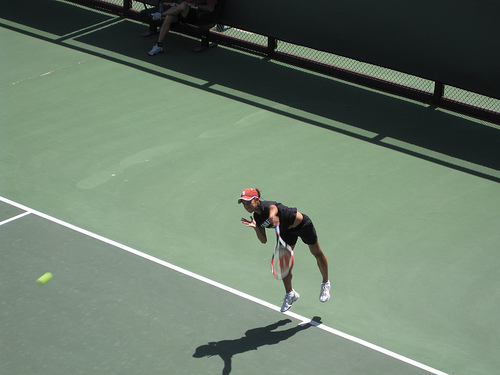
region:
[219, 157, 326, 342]
A woman holding a tennis racket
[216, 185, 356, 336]
a woman jumping up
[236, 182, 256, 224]
a woman wearing a red hat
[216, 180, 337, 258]
a woman wearing a black shirt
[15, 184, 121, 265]
white lines on the tennis court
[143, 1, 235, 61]
a person sitting on a bench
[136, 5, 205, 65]
a person with their legs crossed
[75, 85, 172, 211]
a green tennis court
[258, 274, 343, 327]
two feet off the ground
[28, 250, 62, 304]
a tennis ball in motion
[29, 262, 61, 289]
The ball flying through the air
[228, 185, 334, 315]
The player who just hit the ball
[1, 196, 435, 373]
The white lines on the court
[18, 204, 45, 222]
Where the white lines meet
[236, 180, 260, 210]
The red hat worn by the tennis player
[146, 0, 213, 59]
The person sitting on the bench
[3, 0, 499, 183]
The shadow on the ground behind the court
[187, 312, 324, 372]
The player's shadow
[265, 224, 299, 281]
The racket held by the player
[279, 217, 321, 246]
The player's black shorts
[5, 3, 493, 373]
tennis court on which woman is playing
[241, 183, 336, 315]
woman playing tennis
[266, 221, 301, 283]
woman's tennis racket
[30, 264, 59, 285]
ball in air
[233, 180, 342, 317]
tennis player in black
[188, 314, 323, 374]
shadow of woman tennis player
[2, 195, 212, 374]
baseline of tennis court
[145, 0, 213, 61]
person sitting on bench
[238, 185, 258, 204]
red hat on tennis player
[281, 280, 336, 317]
woman's white tennis shoes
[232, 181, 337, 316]
tennis player hovering over court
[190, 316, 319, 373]
shadow of player on court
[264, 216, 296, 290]
racquet in player's hand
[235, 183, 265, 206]
red cap on player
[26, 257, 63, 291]
yellow tennis ball in air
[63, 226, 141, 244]
white boundary line on court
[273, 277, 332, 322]
white sneakers on player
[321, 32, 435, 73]
chain link fence behind court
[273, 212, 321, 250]
black shorts on player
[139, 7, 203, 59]
person sitting at back of court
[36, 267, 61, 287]
a fast moving ball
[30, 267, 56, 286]
a green tennis ball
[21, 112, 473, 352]
a blue and green tennis court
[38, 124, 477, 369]
young woman playing tennis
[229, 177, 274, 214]
a red and white hat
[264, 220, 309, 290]
a red and white tennis racket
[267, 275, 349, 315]
a pair of white shoes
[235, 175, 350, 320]
a woman in athletic clothing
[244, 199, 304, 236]
black shirt with white writing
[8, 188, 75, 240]
white lines on the court